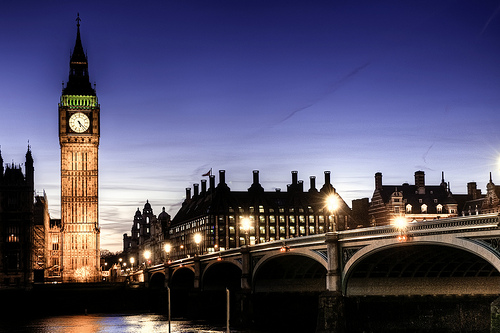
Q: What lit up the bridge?
A: Lights.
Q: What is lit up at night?
A: A tower.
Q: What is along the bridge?
A: Lights.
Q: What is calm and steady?
A: Water.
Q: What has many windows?
A: A building.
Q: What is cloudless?
A: The sky.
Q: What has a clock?
A: A tower.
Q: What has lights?
A: A bridge.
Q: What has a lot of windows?
A: A building.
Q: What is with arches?
A: A bridge.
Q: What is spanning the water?
A: It's a bridge.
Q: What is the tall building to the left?
A: It is a clock tower.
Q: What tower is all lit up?
A: Its a clock tower by the water.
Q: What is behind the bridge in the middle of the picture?
A: Its a building with many lit up windows.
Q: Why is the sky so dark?
A: Its an evening sky.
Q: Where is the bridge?
A: Its over the water.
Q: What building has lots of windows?
A: Its the building in the middle of the picture.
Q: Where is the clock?
A: In the tower.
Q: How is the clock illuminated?
A: With lights.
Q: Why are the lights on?
A: Because it is getting dark.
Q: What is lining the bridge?
A: Lights.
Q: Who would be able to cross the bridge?
A: Pedestrians.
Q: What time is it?
A: 5:23.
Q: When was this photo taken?
A: Evening.